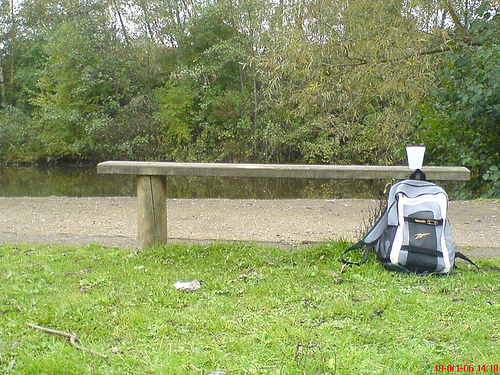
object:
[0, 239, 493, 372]
grass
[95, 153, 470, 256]
bench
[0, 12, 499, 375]
park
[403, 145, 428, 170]
drink on it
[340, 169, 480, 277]
backpack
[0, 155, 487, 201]
lake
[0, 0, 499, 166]
trees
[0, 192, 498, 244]
path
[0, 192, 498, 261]
walking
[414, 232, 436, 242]
logo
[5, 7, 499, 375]
picture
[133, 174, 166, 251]
leg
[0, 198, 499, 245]
gravel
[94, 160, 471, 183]
board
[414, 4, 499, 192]
bushes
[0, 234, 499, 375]
area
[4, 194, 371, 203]
edge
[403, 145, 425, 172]
cup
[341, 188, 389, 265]
straps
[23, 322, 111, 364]
twig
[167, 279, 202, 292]
litter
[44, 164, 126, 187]
reflection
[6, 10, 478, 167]
group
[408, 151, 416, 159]
white